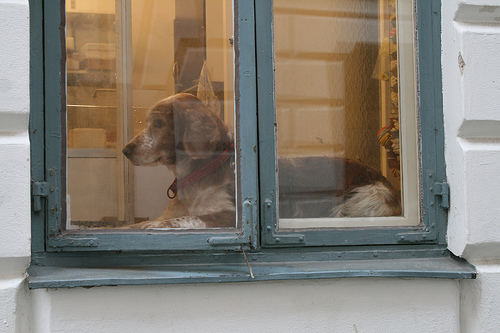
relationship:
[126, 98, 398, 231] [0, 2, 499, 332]
dog in house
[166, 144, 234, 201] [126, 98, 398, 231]
collar on dog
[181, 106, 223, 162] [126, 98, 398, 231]
ear on dog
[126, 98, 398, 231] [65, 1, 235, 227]
dog in window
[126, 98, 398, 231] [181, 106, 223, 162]
dog has an ear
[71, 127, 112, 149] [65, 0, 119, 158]
box on shelf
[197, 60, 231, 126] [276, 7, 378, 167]
cloth on wall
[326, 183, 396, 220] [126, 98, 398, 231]
tail on dog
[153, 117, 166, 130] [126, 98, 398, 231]
eye on dog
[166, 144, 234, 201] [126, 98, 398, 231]
collar on brown dog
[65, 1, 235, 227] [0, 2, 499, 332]
window on house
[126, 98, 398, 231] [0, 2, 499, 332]
dog inside house